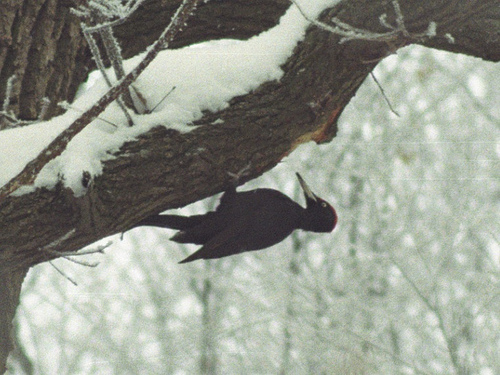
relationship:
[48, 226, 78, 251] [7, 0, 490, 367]
branch on tree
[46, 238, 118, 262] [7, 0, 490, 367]
branch on tree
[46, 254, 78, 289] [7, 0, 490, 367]
branch on tree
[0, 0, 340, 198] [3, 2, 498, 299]
snow on tree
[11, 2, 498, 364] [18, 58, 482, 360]
trees in background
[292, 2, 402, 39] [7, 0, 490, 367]
branch on tree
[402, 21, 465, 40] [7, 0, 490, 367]
branch on tree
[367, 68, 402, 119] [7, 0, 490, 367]
branch on tree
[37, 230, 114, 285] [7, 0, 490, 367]
branch on tree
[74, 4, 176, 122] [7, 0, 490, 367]
branch on tree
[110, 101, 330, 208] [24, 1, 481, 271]
bark on branch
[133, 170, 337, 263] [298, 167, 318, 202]
bird with beak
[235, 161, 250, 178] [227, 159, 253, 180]
claw on claw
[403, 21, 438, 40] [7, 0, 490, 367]
branch on tree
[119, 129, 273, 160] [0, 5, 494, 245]
crevasses on tree bark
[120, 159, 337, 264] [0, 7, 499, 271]
bird on branch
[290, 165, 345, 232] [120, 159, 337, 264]
beak on bird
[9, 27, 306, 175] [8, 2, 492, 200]
snow on branch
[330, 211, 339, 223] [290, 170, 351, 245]
patch on head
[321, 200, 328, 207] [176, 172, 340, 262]
eye on bird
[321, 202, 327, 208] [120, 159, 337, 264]
eye on bird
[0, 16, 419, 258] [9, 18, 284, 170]
branch has snow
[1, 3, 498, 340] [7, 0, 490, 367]
bark on tree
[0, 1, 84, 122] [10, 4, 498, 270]
bark on tree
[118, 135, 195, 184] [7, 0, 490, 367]
bark on tree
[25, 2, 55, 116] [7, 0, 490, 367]
bark on tree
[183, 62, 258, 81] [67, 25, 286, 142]
snow on ground